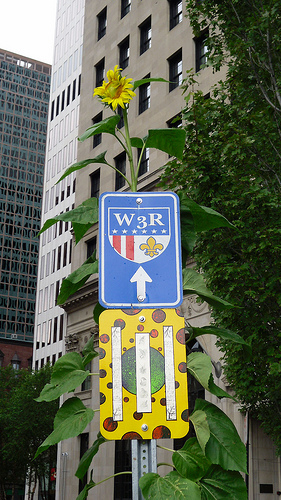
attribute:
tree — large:
[182, 1, 279, 434]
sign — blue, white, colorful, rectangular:
[94, 193, 189, 311]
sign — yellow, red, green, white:
[97, 310, 191, 443]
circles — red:
[149, 310, 166, 341]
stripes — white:
[111, 327, 180, 422]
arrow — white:
[130, 261, 154, 299]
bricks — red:
[3, 341, 35, 379]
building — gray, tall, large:
[0, 48, 51, 371]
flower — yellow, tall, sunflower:
[94, 69, 137, 111]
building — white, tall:
[14, 0, 84, 499]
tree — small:
[10, 364, 51, 500]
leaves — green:
[219, 103, 272, 198]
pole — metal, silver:
[129, 441, 166, 499]